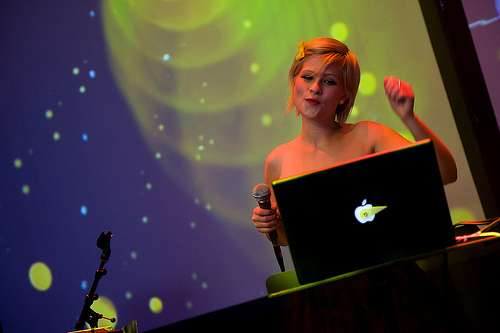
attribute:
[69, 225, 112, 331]
microphone stand — black, metal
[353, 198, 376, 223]
symbol — Apple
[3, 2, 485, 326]
background — glittering, blue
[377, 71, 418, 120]
hand — raised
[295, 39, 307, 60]
bow — yellow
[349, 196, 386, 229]
logo — Apple 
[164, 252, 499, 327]
table — brown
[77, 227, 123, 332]
microphone stand — bare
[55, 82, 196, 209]
background — blue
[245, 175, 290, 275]
microphone — small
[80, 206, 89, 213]
spots — round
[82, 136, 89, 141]
spots — round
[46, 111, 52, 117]
spots — round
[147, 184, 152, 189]
spots — round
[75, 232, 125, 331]
microphone stand — vertical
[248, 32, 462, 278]
woman — young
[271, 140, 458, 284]
laptop — black, apple brand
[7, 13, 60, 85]
wall — blue